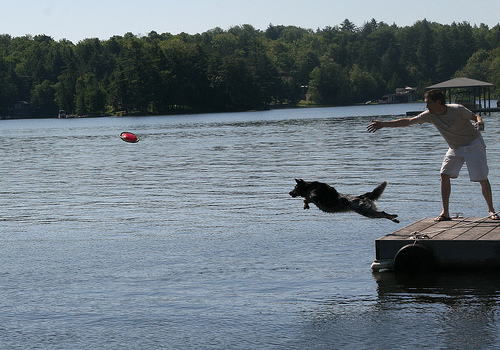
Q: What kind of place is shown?
A: It is a lake.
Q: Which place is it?
A: It is a lake.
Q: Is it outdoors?
A: Yes, it is outdoors.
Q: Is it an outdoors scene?
A: Yes, it is outdoors.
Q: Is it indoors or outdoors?
A: It is outdoors.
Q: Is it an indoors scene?
A: No, it is outdoors.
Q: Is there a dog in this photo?
A: Yes, there is a dog.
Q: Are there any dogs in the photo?
A: Yes, there is a dog.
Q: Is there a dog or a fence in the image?
A: Yes, there is a dog.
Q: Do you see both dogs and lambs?
A: No, there is a dog but no lambs.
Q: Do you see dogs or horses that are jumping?
A: Yes, the dog is jumping.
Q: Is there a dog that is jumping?
A: Yes, there is a dog that is jumping.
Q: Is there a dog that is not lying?
A: Yes, there is a dog that is jumping.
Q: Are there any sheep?
A: No, there are no sheep.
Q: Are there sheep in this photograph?
A: No, there are no sheep.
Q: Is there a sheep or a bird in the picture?
A: No, there are no sheep or birds.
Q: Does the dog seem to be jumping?
A: Yes, the dog is jumping.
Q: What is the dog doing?
A: The dog is jumping.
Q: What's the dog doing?
A: The dog is jumping.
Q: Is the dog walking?
A: No, the dog is jumping.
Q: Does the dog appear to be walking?
A: No, the dog is jumping.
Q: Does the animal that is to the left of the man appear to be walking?
A: No, the dog is jumping.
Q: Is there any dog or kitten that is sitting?
A: No, there is a dog but it is jumping.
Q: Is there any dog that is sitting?
A: No, there is a dog but it is jumping.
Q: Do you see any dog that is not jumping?
A: No, there is a dog but it is jumping.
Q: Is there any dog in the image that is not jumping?
A: No, there is a dog but it is jumping.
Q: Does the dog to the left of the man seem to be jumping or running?
A: The dog is jumping.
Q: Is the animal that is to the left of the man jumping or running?
A: The dog is jumping.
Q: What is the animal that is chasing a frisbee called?
A: The animal is a dog.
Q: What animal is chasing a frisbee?
A: The animal is a dog.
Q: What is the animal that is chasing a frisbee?
A: The animal is a dog.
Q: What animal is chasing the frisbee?
A: The animal is a dog.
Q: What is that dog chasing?
A: The dog is chasing a frisbee.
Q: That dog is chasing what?
A: The dog is chasing a frisbee.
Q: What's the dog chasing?
A: The dog is chasing a frisbee.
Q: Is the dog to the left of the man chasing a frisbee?
A: Yes, the dog is chasing a frisbee.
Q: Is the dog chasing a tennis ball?
A: No, the dog is chasing a frisbee.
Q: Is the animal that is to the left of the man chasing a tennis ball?
A: No, the dog is chasing a frisbee.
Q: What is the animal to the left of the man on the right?
A: The animal is a dog.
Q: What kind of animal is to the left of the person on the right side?
A: The animal is a dog.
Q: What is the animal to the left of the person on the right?
A: The animal is a dog.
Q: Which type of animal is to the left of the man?
A: The animal is a dog.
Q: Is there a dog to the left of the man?
A: Yes, there is a dog to the left of the man.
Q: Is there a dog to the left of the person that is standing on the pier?
A: Yes, there is a dog to the left of the man.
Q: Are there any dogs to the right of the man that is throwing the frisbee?
A: No, the dog is to the left of the man.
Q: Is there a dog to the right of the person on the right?
A: No, the dog is to the left of the man.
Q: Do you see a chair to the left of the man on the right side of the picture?
A: No, there is a dog to the left of the man.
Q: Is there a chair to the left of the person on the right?
A: No, there is a dog to the left of the man.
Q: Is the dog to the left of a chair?
A: No, the dog is to the left of the man.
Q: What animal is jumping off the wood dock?
A: The animal is a dog.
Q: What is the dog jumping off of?
A: The dog is jumping off the dock.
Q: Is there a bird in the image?
A: No, there are no birds.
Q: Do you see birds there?
A: No, there are no birds.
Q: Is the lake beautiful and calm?
A: Yes, the lake is beautiful and calm.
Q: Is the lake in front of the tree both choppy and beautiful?
A: No, the lake is beautiful but calm.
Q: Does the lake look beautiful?
A: Yes, the lake is beautiful.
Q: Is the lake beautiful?
A: Yes, the lake is beautiful.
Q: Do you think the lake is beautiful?
A: Yes, the lake is beautiful.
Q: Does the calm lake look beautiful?
A: Yes, the lake is beautiful.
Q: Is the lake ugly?
A: No, the lake is beautiful.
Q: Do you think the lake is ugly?
A: No, the lake is beautiful.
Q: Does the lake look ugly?
A: No, the lake is beautiful.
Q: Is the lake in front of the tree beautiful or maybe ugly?
A: The lake is beautiful.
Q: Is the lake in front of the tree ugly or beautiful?
A: The lake is beautiful.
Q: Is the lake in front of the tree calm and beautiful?
A: Yes, the lake is calm and beautiful.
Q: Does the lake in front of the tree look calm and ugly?
A: No, the lake is calm but beautiful.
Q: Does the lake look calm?
A: Yes, the lake is calm.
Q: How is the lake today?
A: The lake is calm.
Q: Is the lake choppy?
A: No, the lake is calm.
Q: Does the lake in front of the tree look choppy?
A: No, the lake is calm.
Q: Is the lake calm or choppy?
A: The lake is calm.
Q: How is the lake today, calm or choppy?
A: The lake is calm.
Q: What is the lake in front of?
A: The lake is in front of the tree.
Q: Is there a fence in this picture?
A: No, there are no fences.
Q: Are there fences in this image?
A: No, there are no fences.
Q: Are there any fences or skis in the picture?
A: No, there are no fences or skis.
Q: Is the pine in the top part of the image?
A: Yes, the pine is in the top of the image.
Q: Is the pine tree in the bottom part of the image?
A: No, the pine tree is in the top of the image.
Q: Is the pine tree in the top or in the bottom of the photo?
A: The pine tree is in the top of the image.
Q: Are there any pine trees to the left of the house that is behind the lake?
A: Yes, there is a pine tree to the left of the house.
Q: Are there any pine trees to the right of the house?
A: No, the pine tree is to the left of the house.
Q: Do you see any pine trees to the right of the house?
A: No, the pine tree is to the left of the house.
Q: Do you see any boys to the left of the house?
A: No, there is a pine tree to the left of the house.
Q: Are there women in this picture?
A: No, there are no women.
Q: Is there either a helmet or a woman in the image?
A: No, there are no women or helmets.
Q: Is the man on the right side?
A: Yes, the man is on the right of the image.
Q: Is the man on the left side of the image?
A: No, the man is on the right of the image.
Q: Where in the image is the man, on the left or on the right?
A: The man is on the right of the image.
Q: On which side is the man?
A: The man is on the right of the image.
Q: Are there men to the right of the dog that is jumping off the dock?
A: Yes, there is a man to the right of the dog.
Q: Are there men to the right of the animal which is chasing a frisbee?
A: Yes, there is a man to the right of the dog.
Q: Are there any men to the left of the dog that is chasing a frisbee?
A: No, the man is to the right of the dog.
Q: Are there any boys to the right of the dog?
A: No, there is a man to the right of the dog.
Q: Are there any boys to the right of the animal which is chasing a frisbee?
A: No, there is a man to the right of the dog.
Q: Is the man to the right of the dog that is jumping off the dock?
A: Yes, the man is to the right of the dog.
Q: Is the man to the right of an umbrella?
A: No, the man is to the right of the dog.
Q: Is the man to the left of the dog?
A: No, the man is to the right of the dog.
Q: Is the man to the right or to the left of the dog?
A: The man is to the right of the dog.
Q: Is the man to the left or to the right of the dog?
A: The man is to the right of the dog.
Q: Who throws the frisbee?
A: The man throws the frisbee.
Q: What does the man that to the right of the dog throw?
A: The man throws the frisbee.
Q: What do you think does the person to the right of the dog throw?
A: The man throws the frisbee.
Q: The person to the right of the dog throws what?
A: The man throws the frisbee.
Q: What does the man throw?
A: The man throws the frisbee.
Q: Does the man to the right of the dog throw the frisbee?
A: Yes, the man throws the frisbee.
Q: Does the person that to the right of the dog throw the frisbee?
A: Yes, the man throws the frisbee.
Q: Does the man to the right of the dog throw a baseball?
A: No, the man throws the frisbee.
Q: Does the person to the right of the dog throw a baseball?
A: No, the man throws the frisbee.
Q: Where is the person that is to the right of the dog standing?
A: The man is standing on the pier.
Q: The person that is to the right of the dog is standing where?
A: The man is standing on the pier.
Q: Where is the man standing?
A: The man is standing on the pier.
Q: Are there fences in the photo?
A: No, there are no fences.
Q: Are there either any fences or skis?
A: No, there are no fences or skis.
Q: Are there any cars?
A: No, there are no cars.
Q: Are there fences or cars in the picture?
A: No, there are no cars or fences.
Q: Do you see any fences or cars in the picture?
A: No, there are no cars or fences.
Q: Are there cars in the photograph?
A: No, there are no cars.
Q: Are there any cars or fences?
A: No, there are no cars or fences.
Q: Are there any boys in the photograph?
A: No, there are no boys.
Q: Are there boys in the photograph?
A: No, there are no boys.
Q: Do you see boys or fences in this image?
A: No, there are no boys or fences.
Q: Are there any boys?
A: No, there are no boys.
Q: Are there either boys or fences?
A: No, there are no boys or fences.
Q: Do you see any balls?
A: No, there are no balls.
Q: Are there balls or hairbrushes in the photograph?
A: No, there are no balls or hairbrushes.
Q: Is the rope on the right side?
A: Yes, the rope is on the right of the image.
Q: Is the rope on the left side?
A: No, the rope is on the right of the image.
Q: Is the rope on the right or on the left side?
A: The rope is on the right of the image.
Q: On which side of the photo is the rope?
A: The rope is on the right of the image.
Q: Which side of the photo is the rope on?
A: The rope is on the right of the image.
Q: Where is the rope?
A: The rope is on the dock.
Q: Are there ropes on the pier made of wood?
A: Yes, there is a rope on the dock.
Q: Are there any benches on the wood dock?
A: No, there is a rope on the pier.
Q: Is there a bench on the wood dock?
A: No, there is a rope on the pier.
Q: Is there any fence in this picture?
A: No, there are no fences.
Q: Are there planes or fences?
A: No, there are no fences or planes.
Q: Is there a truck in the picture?
A: No, there are no trucks.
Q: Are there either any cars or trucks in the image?
A: No, there are no trucks or cars.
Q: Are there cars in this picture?
A: No, there are no cars.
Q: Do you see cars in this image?
A: No, there are no cars.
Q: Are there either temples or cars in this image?
A: No, there are no cars or temples.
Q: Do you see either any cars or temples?
A: No, there are no cars or temples.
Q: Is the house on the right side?
A: Yes, the house is on the right of the image.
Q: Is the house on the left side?
A: No, the house is on the right of the image.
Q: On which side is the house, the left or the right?
A: The house is on the right of the image.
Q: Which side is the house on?
A: The house is on the right of the image.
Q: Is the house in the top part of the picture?
A: Yes, the house is in the top of the image.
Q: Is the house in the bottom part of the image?
A: No, the house is in the top of the image.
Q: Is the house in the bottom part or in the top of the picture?
A: The house is in the top of the image.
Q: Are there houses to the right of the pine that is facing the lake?
A: Yes, there is a house to the right of the pine tree.